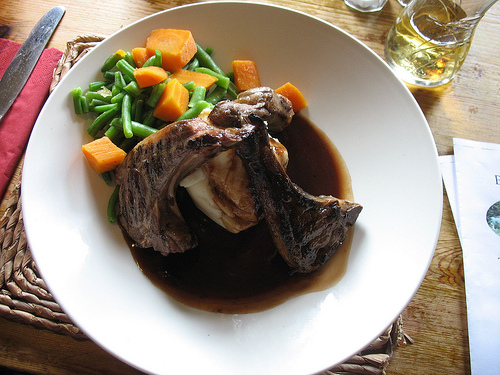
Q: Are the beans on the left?
A: Yes, the beans are on the left of the image.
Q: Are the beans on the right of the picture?
A: No, the beans are on the left of the image.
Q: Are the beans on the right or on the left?
A: The beans are on the left of the image.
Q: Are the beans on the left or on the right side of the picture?
A: The beans are on the left of the image.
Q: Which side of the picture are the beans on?
A: The beans are on the left of the image.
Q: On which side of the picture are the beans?
A: The beans are on the left of the image.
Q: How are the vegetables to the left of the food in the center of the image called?
A: The vegetables are beans.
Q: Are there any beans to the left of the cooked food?
A: Yes, there are beans to the left of the food.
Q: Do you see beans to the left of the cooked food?
A: Yes, there are beans to the left of the food.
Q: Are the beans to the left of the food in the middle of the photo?
A: Yes, the beans are to the left of the food.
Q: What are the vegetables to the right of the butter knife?
A: The vegetables are beans.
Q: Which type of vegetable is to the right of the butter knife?
A: The vegetables are beans.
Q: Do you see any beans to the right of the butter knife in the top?
A: Yes, there are beans to the right of the butter knife.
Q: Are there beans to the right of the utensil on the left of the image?
A: Yes, there are beans to the right of the butter knife.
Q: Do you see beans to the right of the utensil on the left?
A: Yes, there are beans to the right of the butter knife.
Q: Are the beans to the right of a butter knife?
A: Yes, the beans are to the right of a butter knife.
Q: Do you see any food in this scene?
A: Yes, there is food.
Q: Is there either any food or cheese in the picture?
A: Yes, there is food.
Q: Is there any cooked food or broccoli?
A: Yes, there is cooked food.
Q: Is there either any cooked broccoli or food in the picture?
A: Yes, there is cooked food.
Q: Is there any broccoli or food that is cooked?
A: Yes, the food is cooked.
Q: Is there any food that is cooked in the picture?
A: Yes, there is cooked food.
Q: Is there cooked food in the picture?
A: Yes, there is cooked food.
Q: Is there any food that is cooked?
A: Yes, there is food that is cooked.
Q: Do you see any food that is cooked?
A: Yes, there is food that is cooked.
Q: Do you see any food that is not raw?
A: Yes, there is cooked food.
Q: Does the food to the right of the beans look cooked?
A: Yes, the food is cooked.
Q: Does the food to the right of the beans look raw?
A: No, the food is cooked.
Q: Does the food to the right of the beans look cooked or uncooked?
A: The food is cooked.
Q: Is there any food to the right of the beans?
A: Yes, there is food to the right of the beans.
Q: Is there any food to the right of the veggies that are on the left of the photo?
A: Yes, there is food to the right of the beans.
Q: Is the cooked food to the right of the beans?
A: Yes, the food is to the right of the beans.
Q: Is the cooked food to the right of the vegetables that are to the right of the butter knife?
A: Yes, the food is to the right of the beans.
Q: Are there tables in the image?
A: Yes, there is a table.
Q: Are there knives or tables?
A: Yes, there is a table.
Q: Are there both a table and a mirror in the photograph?
A: No, there is a table but no mirrors.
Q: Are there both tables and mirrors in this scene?
A: No, there is a table but no mirrors.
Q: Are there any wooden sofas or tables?
A: Yes, there is a wood table.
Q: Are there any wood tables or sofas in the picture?
A: Yes, there is a wood table.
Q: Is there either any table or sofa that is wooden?
A: Yes, the table is wooden.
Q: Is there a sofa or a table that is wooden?
A: Yes, the table is wooden.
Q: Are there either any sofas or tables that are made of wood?
A: Yes, the table is made of wood.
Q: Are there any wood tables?
A: Yes, there is a table that is made of wood.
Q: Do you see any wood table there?
A: Yes, there is a table that is made of wood.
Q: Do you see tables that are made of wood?
A: Yes, there is a table that is made of wood.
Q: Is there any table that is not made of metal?
A: Yes, there is a table that is made of wood.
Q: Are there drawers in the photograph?
A: No, there are no drawers.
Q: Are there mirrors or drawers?
A: No, there are no drawers or mirrors.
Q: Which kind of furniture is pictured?
A: The furniture is a table.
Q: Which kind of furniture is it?
A: The piece of furniture is a table.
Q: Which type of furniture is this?
A: This is a table.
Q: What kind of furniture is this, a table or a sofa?
A: This is a table.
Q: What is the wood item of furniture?
A: The piece of furniture is a table.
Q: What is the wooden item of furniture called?
A: The piece of furniture is a table.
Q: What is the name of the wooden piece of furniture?
A: The piece of furniture is a table.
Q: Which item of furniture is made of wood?
A: The piece of furniture is a table.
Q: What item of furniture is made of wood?
A: The piece of furniture is a table.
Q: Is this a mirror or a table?
A: This is a table.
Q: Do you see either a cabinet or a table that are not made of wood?
A: No, there is a table but it is made of wood.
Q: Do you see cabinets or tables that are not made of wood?
A: No, there is a table but it is made of wood.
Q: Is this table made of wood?
A: Yes, the table is made of wood.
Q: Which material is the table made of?
A: The table is made of wood.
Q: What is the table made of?
A: The table is made of wood.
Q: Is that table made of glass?
A: No, the table is made of wood.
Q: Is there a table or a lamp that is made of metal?
A: No, there is a table but it is made of wood.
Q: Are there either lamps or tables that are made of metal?
A: No, there is a table but it is made of wood.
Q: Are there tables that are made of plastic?
A: No, there is a table but it is made of wood.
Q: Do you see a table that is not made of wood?
A: No, there is a table but it is made of wood.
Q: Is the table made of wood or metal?
A: The table is made of wood.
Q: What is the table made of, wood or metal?
A: The table is made of wood.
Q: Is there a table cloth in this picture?
A: No, there are no tablecloths.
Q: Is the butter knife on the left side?
A: Yes, the butter knife is on the left of the image.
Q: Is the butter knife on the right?
A: No, the butter knife is on the left of the image.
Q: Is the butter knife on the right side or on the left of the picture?
A: The butter knife is on the left of the image.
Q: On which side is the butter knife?
A: The butter knife is on the left of the image.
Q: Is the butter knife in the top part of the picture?
A: Yes, the butter knife is in the top of the image.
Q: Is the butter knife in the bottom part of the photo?
A: No, the butter knife is in the top of the image.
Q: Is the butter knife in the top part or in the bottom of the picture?
A: The butter knife is in the top of the image.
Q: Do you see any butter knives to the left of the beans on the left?
A: Yes, there is a butter knife to the left of the beans.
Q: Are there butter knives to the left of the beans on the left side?
A: Yes, there is a butter knife to the left of the beans.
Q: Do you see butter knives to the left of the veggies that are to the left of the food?
A: Yes, there is a butter knife to the left of the beans.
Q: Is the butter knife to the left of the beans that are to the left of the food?
A: Yes, the butter knife is to the left of the beans.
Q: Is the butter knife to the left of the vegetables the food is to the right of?
A: Yes, the butter knife is to the left of the beans.